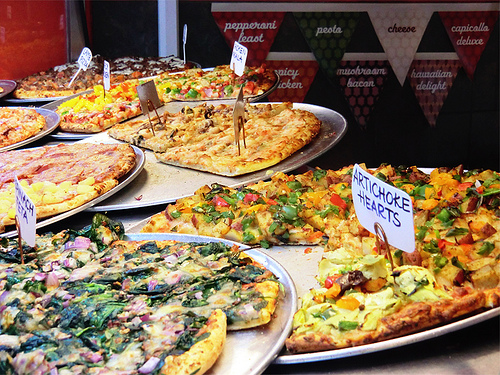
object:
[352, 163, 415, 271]
sign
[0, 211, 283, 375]
green spinach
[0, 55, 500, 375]
pizza pies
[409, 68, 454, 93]
words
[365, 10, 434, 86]
flag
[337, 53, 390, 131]
banner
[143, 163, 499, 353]
artichoke pizza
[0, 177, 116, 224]
toppings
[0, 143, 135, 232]
pizza slice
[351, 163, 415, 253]
paper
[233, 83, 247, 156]
sign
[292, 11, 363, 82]
banner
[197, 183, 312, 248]
toppings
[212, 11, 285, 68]
flag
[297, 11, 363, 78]
flag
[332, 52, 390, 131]
flag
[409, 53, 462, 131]
flag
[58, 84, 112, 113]
pineapple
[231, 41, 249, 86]
sign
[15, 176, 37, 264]
sign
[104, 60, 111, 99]
sign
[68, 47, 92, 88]
sign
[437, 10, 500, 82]
flag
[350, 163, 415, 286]
banner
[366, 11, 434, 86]
banner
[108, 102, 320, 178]
slices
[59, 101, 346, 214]
tray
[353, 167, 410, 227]
letter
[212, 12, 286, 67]
banner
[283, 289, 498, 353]
pizza edge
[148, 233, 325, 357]
missing slice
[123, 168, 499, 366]
tray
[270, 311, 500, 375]
shade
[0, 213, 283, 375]
pizza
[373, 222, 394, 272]
metal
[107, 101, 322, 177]
pizza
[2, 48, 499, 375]
display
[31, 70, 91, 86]
meat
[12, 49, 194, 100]
cheese